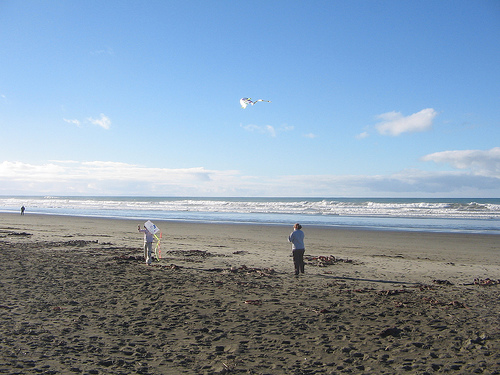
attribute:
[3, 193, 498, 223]
wave — white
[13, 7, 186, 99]
sky — blue, cloudless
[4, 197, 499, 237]
water — blue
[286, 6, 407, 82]
sky — clear, blue, cloudless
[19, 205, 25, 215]
person — far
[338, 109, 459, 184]
clouds — white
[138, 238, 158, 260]
pants — tan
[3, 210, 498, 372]
sand — brown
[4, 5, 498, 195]
sky — blue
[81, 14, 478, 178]
sky — blue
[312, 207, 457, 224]
water — large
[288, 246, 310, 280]
pants — black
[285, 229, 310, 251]
sweater — tan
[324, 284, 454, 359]
prints — tan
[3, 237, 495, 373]
prints — tan